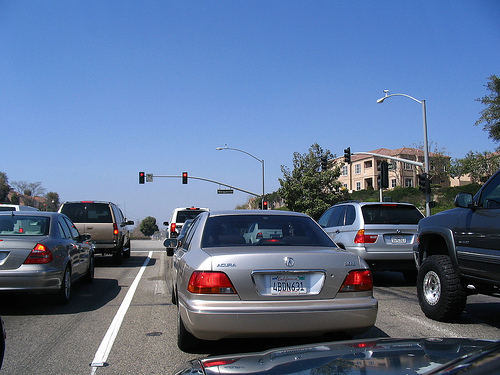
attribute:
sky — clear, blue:
[1, 3, 483, 193]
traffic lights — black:
[138, 171, 189, 185]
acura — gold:
[165, 206, 379, 345]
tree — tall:
[275, 142, 348, 205]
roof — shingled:
[370, 147, 427, 162]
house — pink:
[333, 148, 443, 186]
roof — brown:
[347, 151, 431, 156]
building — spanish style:
[319, 137, 438, 189]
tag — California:
[297, 273, 306, 280]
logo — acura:
[287, 257, 295, 268]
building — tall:
[325, 145, 442, 198]